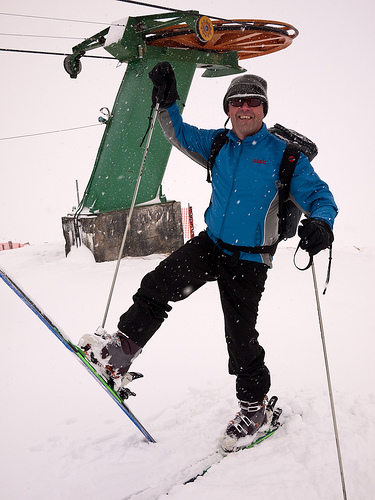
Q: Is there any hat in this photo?
A: Yes, there is a hat.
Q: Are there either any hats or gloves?
A: Yes, there is a hat.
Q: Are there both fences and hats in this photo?
A: No, there is a hat but no fences.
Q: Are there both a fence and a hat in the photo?
A: No, there is a hat but no fences.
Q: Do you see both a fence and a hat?
A: No, there is a hat but no fences.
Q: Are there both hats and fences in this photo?
A: No, there is a hat but no fences.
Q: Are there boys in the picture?
A: No, there are no boys.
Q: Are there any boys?
A: No, there are no boys.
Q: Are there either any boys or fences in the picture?
A: No, there are no boys or fences.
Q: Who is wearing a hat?
A: The man is wearing a hat.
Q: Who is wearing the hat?
A: The man is wearing a hat.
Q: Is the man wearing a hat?
A: Yes, the man is wearing a hat.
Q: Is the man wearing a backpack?
A: No, the man is wearing a hat.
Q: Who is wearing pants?
A: The man is wearing pants.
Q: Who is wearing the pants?
A: The man is wearing pants.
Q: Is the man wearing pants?
A: Yes, the man is wearing pants.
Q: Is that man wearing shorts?
A: No, the man is wearing pants.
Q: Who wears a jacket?
A: The man wears a jacket.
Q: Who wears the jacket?
A: The man wears a jacket.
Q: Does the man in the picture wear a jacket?
A: Yes, the man wears a jacket.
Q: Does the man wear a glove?
A: No, the man wears a jacket.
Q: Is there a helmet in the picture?
A: No, there are no helmets.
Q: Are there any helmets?
A: No, there are no helmets.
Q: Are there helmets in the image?
A: No, there are no helmets.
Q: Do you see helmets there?
A: No, there are no helmets.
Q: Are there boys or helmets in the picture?
A: No, there are no helmets or boys.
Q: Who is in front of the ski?
A: The skier is in front of the ski.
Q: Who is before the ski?
A: The skier is in front of the ski.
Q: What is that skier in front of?
A: The skier is in front of the ski.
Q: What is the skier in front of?
A: The skier is in front of the ski.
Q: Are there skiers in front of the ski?
A: Yes, there is a skier in front of the ski.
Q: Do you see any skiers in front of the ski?
A: Yes, there is a skier in front of the ski.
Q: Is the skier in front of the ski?
A: Yes, the skier is in front of the ski.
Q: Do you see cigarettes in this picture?
A: No, there are no cigarettes.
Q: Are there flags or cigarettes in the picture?
A: No, there are no cigarettes or flags.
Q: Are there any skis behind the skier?
A: Yes, there is a ski behind the skier.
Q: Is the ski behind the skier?
A: Yes, the ski is behind the skier.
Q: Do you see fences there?
A: No, there are no fences.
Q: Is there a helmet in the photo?
A: No, there are no helmets.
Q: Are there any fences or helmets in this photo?
A: No, there are no helmets or fences.